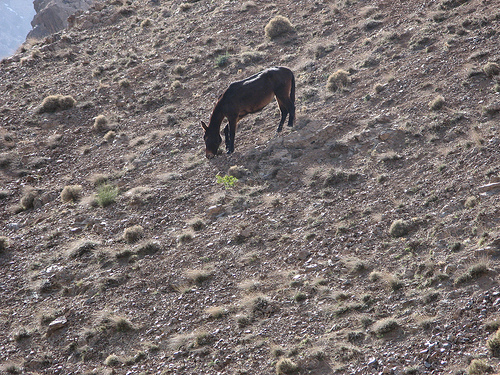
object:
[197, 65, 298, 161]
donkey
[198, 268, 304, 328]
grass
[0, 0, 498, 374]
dirt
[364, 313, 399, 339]
grass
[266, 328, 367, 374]
grass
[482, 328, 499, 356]
grass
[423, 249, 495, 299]
grass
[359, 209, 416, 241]
grass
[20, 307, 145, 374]
grass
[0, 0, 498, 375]
scene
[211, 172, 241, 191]
plant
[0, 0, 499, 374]
ground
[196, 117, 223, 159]
head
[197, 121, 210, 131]
ear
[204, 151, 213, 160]
mouth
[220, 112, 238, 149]
legs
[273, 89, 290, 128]
legs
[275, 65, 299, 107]
tail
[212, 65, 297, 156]
body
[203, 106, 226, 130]
neck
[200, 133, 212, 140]
eye